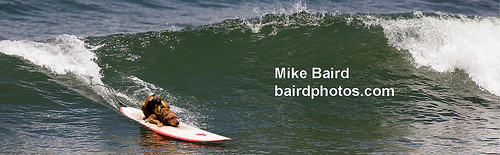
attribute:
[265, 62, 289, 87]
letter — white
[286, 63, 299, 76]
letter — white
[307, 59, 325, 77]
letter — white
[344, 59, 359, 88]
letter — white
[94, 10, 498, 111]
water — white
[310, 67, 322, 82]
letter — white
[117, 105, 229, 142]
surfboard — red, white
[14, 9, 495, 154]
water — white, ocean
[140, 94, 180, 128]
dog — laying down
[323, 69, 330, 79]
letter — white